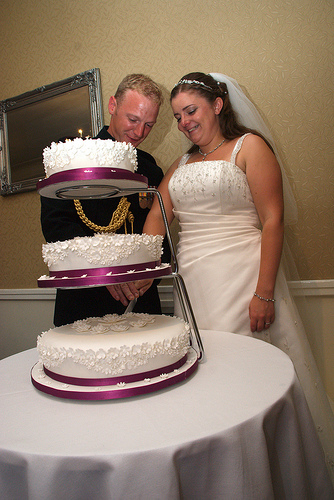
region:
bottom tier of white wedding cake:
[27, 320, 229, 407]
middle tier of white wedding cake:
[35, 228, 170, 300]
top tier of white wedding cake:
[32, 138, 143, 194]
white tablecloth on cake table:
[75, 404, 256, 498]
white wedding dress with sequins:
[169, 130, 294, 345]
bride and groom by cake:
[90, 64, 268, 212]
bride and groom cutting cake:
[71, 68, 278, 354]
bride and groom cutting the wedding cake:
[30, 73, 332, 427]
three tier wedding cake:
[33, 137, 198, 400]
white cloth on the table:
[4, 335, 332, 497]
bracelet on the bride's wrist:
[248, 289, 273, 305]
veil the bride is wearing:
[212, 62, 300, 292]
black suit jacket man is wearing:
[37, 123, 166, 324]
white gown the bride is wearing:
[166, 148, 331, 466]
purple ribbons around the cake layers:
[28, 162, 187, 384]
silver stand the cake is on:
[60, 176, 209, 377]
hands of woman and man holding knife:
[104, 245, 158, 308]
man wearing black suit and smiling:
[35, 72, 169, 321]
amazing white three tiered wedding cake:
[29, 136, 205, 401]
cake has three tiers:
[27, 135, 204, 400]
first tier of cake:
[30, 309, 196, 397]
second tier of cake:
[33, 232, 173, 289]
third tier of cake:
[36, 138, 148, 202]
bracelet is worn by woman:
[252, 289, 274, 304]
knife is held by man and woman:
[122, 286, 143, 316]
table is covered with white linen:
[0, 327, 333, 498]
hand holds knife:
[99, 267, 138, 304]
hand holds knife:
[132, 262, 158, 296]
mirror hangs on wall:
[0, 67, 105, 194]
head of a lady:
[163, 64, 263, 153]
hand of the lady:
[229, 267, 288, 346]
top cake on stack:
[35, 129, 146, 178]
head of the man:
[85, 67, 173, 158]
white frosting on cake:
[59, 341, 135, 375]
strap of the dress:
[217, 119, 267, 170]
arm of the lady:
[200, 141, 310, 325]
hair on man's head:
[115, 69, 165, 102]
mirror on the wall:
[0, 66, 102, 180]